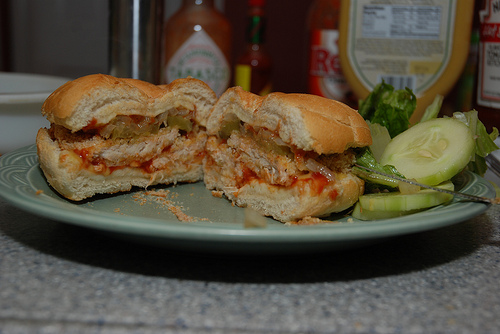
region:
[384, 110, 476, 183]
one slice of a pickle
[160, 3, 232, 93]
a bottle of tabasco sauce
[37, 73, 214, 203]
one-half of a chicken sandwich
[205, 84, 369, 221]
one-half of a chicken sandwich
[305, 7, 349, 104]
bottle of frank's red hot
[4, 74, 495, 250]
sandwich on a green plate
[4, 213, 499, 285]
shadow of a plate on the counter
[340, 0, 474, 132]
part of a menu against a wall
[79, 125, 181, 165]
a piece of chicken on the sandwich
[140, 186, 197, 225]
some crumbs on the plate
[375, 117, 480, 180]
round slice of cucumber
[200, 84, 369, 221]
right half of chicken sandwich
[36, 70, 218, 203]
left half of chicken sandwich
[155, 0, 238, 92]
bottle of tobasco sauce in distance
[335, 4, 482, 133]
bottle of mustard upside down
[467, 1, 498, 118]
side portion of bottle of ketchup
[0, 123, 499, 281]
green ceramic dinner plate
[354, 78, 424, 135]
piece of dark green lettuce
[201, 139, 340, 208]
red sauce on sandwich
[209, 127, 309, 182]
piece of breaded chicken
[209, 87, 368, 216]
sandwich on the plate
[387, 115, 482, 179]
cuke on the plate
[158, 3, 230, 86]
bottle of tobasco sauce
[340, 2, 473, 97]
bottle of mustard on the table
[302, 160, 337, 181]
onion on the sandwich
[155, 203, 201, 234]
plate the food is on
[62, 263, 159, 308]
gray tabletop the plate is on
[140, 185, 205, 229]
crumbs on the plate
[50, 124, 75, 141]
hamburger on the sandwich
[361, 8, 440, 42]
ingredients label on the bottle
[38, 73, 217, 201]
sandwich half next to sandwich half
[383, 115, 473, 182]
cucumber on top of cucumber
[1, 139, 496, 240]
gray stoneware plate under sandwich halves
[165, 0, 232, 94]
glass bottle behind sandwich half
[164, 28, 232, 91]
white label on bottle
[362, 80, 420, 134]
green lettuce next to cucumber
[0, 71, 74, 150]
white bowl behind plate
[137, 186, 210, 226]
dry crumbs on plate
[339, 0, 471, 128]
yellow mustard bottle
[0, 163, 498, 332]
plate on table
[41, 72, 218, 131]
a piece of cake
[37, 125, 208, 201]
a piece of cake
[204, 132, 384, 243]
a piece of cake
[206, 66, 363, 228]
a piece of cake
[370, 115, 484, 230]
a piece of vegetable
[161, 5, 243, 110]
a bottle of ketchup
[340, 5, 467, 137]
a bottle of ketchup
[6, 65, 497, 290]
a plate of food